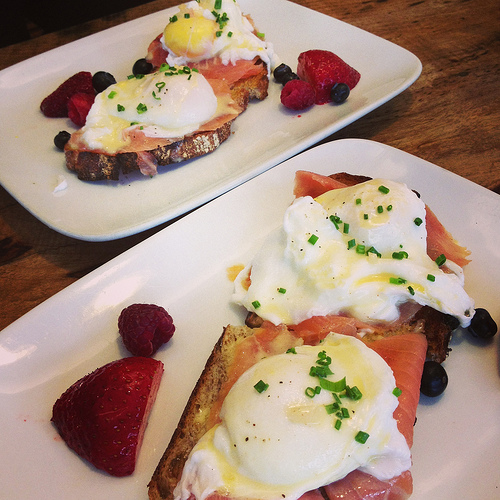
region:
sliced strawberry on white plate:
[49, 360, 169, 479]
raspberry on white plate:
[119, 304, 174, 355]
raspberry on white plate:
[280, 78, 316, 109]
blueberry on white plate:
[416, 359, 449, 396]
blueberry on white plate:
[473, 307, 498, 345]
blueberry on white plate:
[53, 130, 69, 148]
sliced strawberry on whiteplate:
[39, 71, 98, 119]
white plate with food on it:
[1, 0, 417, 238]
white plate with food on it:
[0, 139, 497, 496]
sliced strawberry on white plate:
[295, 48, 359, 102]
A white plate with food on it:
[156, 173, 478, 498]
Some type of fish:
[192, 250, 387, 493]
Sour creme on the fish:
[225, 346, 352, 461]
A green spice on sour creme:
[289, 358, 363, 427]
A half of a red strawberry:
[61, 350, 151, 488]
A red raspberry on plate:
[116, 290, 179, 350]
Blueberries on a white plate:
[421, 355, 448, 400]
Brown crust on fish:
[126, 135, 208, 178]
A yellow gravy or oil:
[218, 242, 254, 294]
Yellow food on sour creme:
[157, 12, 219, 57]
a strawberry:
[63, 358, 176, 477]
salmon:
[221, 332, 259, 356]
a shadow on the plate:
[16, 325, 81, 366]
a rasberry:
[118, 295, 176, 348]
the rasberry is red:
[110, 299, 177, 352]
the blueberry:
[328, 83, 357, 100]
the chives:
[318, 348, 365, 433]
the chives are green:
[311, 350, 358, 437]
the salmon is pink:
[393, 340, 419, 385]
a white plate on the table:
[421, 421, 481, 491]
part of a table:
[471, 126, 496, 143]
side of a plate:
[101, 350, 111, 368]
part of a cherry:
[111, 383, 130, 428]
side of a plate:
[179, 443, 191, 452]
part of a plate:
[29, 410, 53, 435]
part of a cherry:
[429, 373, 437, 390]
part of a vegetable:
[340, 385, 348, 395]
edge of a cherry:
[128, 423, 143, 439]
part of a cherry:
[432, 363, 442, 390]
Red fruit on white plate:
[78, 290, 189, 367]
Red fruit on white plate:
[38, 351, 195, 477]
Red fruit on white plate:
[280, 74, 316, 112]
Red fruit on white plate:
[273, 37, 366, 101]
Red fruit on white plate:
[51, 91, 112, 125]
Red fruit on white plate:
[27, 64, 109, 111]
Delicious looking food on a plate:
[20, 10, 312, 173]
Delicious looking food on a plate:
[72, 174, 439, 497]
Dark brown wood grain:
[392, 98, 482, 167]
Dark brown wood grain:
[438, 24, 488, 93]